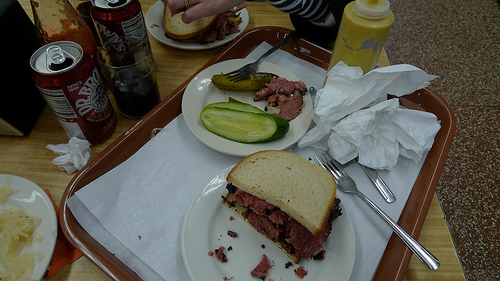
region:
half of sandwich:
[217, 156, 349, 256]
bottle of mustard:
[323, 3, 393, 88]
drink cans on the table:
[28, 0, 158, 150]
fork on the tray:
[317, 149, 439, 269]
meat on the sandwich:
[219, 191, 319, 256]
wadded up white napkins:
[311, 58, 446, 165]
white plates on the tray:
[175, 60, 364, 279]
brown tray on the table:
[55, 14, 460, 279]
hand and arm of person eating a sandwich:
[167, 2, 329, 36]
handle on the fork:
[368, 202, 441, 270]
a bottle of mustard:
[328, 0, 399, 73]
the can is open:
[27, 34, 123, 150]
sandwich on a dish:
[170, 148, 362, 280]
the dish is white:
[177, 148, 371, 280]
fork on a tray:
[320, 152, 443, 274]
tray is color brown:
[56, 20, 466, 280]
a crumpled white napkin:
[291, 51, 447, 181]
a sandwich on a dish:
[140, 0, 254, 59]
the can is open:
[85, 0, 161, 76]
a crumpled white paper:
[43, 133, 94, 182]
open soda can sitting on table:
[30, 37, 117, 144]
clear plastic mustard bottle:
[321, 0, 395, 92]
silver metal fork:
[316, 151, 440, 270]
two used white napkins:
[296, 60, 441, 167]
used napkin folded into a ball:
[46, 136, 90, 174]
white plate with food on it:
[0, 173, 55, 280]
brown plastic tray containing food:
[62, 26, 458, 279]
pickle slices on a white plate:
[200, 102, 289, 146]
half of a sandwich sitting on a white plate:
[180, 149, 356, 278]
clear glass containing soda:
[95, 33, 163, 119]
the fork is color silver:
[316, 153, 442, 278]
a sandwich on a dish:
[173, 145, 360, 279]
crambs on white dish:
[205, 236, 273, 279]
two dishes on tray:
[49, 20, 462, 279]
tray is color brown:
[47, 22, 461, 279]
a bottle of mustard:
[324, 2, 396, 72]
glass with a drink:
[94, 31, 167, 121]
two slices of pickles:
[196, 93, 288, 145]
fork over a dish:
[194, 36, 306, 93]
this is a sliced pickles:
[205, 123, 280, 153]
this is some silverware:
[365, 208, 403, 278]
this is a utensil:
[352, 163, 425, 248]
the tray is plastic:
[105, 187, 110, 260]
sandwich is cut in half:
[222, 150, 342, 260]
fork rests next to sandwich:
[315, 147, 440, 271]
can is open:
[29, 42, 121, 147]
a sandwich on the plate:
[211, 121, 350, 258]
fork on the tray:
[315, 136, 455, 278]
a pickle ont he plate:
[191, 88, 290, 158]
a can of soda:
[14, 13, 116, 152]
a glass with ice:
[90, 40, 185, 126]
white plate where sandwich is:
[178, 161, 358, 279]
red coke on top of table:
[29, 40, 117, 147]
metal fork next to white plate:
[313, 151, 441, 268]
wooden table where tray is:
[1, 3, 465, 277]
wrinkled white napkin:
[295, 57, 440, 177]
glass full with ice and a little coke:
[93, 38, 165, 116]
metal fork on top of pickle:
[226, 30, 303, 80]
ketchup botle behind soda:
[31, 2, 111, 90]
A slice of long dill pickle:
[191, 96, 292, 143]